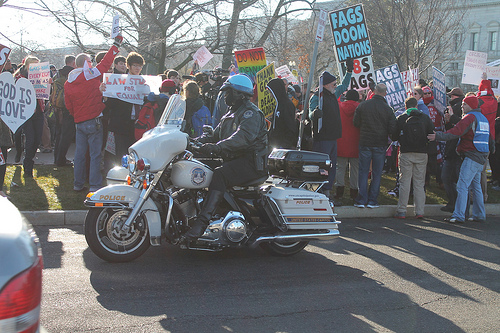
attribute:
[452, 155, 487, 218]
pants — blue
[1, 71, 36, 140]
sign — heart shaped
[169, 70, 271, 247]
officer — police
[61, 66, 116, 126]
jacket — red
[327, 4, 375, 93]
sign — blue, black, large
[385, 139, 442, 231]
pants — khaki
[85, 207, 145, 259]
wheel — black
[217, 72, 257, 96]
helmet — blue, black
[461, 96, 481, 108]
hat — red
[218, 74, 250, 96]
helmet — blue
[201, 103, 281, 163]
coat — black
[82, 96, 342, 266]
bike — white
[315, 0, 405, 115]
sign — rainbow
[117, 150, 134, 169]
light — blue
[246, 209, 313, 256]
tire — back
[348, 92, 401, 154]
jacket — black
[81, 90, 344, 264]
motorcycle — white, police